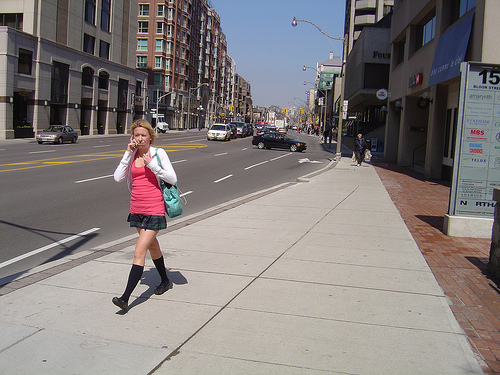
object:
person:
[354, 133, 368, 167]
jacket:
[354, 138, 368, 153]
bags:
[351, 149, 373, 163]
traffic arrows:
[298, 158, 323, 164]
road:
[0, 125, 500, 375]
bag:
[154, 146, 183, 218]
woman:
[112, 118, 185, 313]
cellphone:
[131, 138, 138, 148]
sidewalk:
[0, 156, 500, 375]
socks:
[121, 255, 170, 303]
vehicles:
[205, 121, 307, 152]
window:
[137, 3, 150, 19]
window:
[136, 36, 148, 51]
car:
[251, 132, 307, 152]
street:
[0, 130, 340, 297]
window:
[137, 19, 149, 34]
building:
[0, 0, 253, 139]